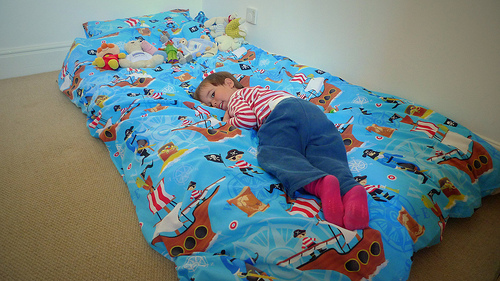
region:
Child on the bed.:
[180, 55, 397, 278]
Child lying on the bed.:
[191, 61, 429, 273]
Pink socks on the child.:
[293, 148, 441, 270]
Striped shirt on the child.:
[205, 50, 321, 148]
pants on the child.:
[254, 99, 425, 236]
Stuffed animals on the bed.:
[70, 20, 310, 89]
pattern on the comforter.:
[88, 57, 315, 278]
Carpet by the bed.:
[11, 62, 213, 255]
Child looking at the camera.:
[166, 54, 341, 139]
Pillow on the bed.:
[79, 20, 285, 53]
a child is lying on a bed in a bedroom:
[2, 3, 491, 270]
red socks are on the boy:
[301, 171, 370, 231]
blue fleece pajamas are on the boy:
[256, 100, 362, 198]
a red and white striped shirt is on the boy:
[225, 85, 292, 129]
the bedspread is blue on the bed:
[65, 32, 494, 279]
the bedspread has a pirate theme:
[71, 35, 499, 280]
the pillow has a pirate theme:
[75, 5, 190, 40]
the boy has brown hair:
[194, 69, 238, 86]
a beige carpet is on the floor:
[3, 65, 496, 275]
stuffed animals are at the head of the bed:
[88, 13, 251, 67]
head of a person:
[192, 66, 242, 113]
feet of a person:
[305, 169, 379, 234]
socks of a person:
[302, 165, 381, 235]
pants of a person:
[253, 90, 354, 201]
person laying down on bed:
[191, 67, 379, 232]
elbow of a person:
[226, 86, 262, 138]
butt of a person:
[270, 95, 342, 137]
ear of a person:
[219, 70, 241, 87]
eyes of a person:
[204, 81, 219, 108]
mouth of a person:
[217, 96, 227, 109]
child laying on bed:
[199, 70, 378, 235]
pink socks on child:
[303, 173, 372, 232]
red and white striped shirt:
[222, 84, 294, 129]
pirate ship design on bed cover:
[138, 165, 223, 257]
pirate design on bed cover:
[204, 148, 259, 180]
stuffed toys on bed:
[92, 35, 165, 67]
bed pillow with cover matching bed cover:
[81, 7, 193, 35]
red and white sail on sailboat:
[144, 175, 174, 215]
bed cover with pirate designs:
[57, 25, 497, 280]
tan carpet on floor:
[0, 72, 182, 279]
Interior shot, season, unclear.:
[7, 7, 499, 279]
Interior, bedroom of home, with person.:
[5, 0, 498, 277]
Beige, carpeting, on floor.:
[32, 162, 105, 254]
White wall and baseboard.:
[9, 0, 64, 81]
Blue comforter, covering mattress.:
[70, 55, 156, 200]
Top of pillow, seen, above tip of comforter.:
[82, 5, 185, 30]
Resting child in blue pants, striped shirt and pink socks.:
[187, 58, 392, 251]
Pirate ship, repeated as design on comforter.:
[142, 178, 219, 257]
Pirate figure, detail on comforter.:
[204, 143, 264, 197]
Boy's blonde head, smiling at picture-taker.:
[198, 63, 243, 111]